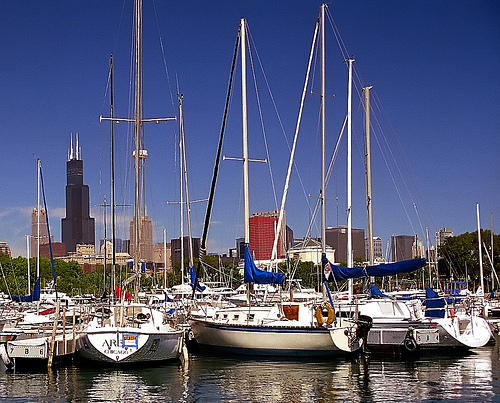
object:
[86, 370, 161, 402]
reflection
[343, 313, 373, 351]
motor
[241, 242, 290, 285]
cover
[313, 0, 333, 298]
pole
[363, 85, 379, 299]
pole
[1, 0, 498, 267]
sky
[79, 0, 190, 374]
boat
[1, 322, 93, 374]
boat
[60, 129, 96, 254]
building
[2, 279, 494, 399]
marina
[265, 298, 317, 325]
cabin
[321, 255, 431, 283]
sail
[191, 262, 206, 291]
sail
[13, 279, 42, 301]
sail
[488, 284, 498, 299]
sail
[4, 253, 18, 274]
leaves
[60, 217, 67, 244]
edge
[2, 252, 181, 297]
forest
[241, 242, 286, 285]
sail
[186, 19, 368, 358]
boat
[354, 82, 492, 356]
boat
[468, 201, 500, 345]
boat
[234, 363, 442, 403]
reflections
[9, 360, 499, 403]
water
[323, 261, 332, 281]
flag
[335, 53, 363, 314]
pole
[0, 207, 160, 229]
cloud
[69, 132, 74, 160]
antennas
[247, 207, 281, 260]
building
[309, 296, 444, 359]
boat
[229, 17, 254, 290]
mast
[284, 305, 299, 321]
door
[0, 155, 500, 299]
city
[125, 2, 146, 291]
masts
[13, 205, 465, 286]
distance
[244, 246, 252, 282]
blue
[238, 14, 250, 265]
white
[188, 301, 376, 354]
docked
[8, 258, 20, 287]
green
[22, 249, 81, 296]
part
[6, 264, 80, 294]
part